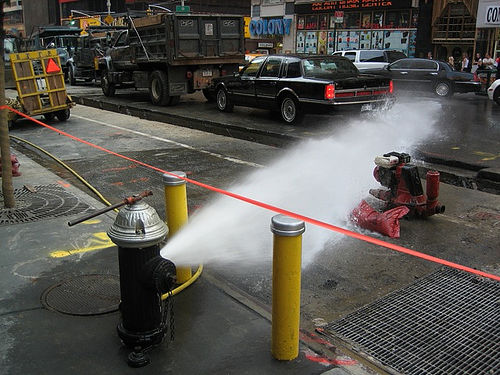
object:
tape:
[397, 247, 495, 279]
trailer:
[6, 45, 74, 123]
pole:
[269, 214, 305, 361]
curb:
[307, 338, 370, 374]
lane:
[82, 96, 331, 345]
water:
[340, 191, 347, 199]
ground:
[441, 219, 458, 250]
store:
[287, 0, 420, 57]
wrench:
[68, 188, 152, 227]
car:
[201, 53, 393, 126]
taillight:
[326, 83, 334, 98]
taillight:
[389, 81, 393, 92]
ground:
[334, 268, 386, 290]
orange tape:
[37, 122, 115, 155]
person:
[448, 55, 455, 69]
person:
[460, 55, 468, 72]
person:
[473, 52, 482, 73]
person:
[483, 53, 495, 70]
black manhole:
[45, 273, 125, 316]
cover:
[41, 273, 121, 314]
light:
[327, 93, 334, 98]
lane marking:
[115, 123, 266, 168]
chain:
[168, 292, 177, 342]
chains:
[155, 288, 168, 343]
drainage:
[0, 182, 89, 224]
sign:
[270, 212, 305, 362]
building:
[282, 7, 423, 59]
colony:
[249, 18, 291, 35]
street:
[0, 0, 499, 372]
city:
[4, 1, 499, 368]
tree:
[0, 1, 15, 208]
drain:
[323, 261, 498, 374]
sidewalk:
[1, 260, 199, 373]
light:
[70, 20, 75, 25]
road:
[51, 64, 498, 175]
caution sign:
[46, 58, 61, 72]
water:
[326, 167, 334, 179]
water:
[168, 241, 188, 257]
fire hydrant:
[68, 190, 177, 365]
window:
[360, 11, 371, 28]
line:
[340, 231, 499, 281]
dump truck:
[89, 3, 249, 106]